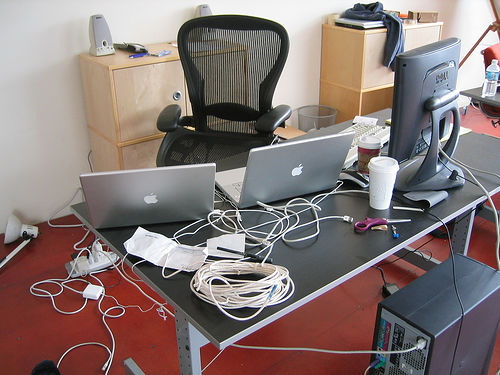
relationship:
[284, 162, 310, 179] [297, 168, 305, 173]
logo of a bitten apple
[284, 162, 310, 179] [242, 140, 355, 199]
logo of a laptop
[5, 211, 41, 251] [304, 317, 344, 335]
lamp on floor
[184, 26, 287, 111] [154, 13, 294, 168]
chair has chair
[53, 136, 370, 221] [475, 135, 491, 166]
two laptops on desk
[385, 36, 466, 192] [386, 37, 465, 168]
desk computers has computer monitor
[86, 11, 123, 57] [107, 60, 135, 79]
speakers on cubicle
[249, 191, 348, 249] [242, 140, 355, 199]
cords hooked to eletronics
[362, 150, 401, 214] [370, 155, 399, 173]
coffee cup with lid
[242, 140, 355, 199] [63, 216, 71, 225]
laptop on table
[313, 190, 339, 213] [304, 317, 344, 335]
cords on floor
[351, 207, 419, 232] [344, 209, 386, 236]
scissors have handles